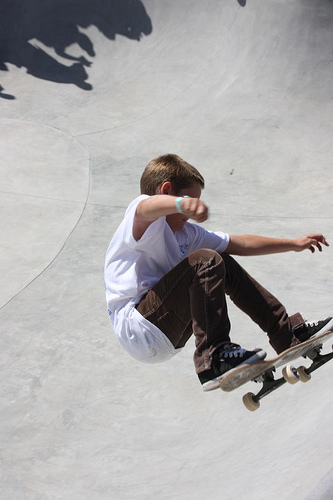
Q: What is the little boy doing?
A: The boy is skateboarding.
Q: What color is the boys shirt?
A: The boys shirt is white.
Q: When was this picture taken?
A: It was taken in the day time.